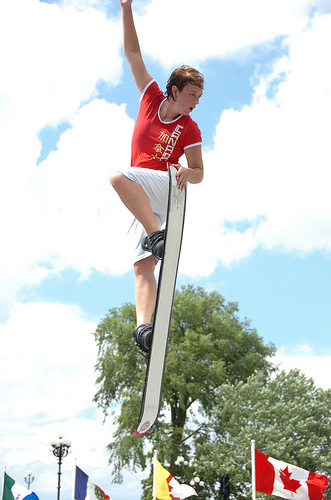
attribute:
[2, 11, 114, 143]
clouds — white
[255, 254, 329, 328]
sky — blue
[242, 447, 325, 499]
canadian flag — red, white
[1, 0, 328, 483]
cloud — large, white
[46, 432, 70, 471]
lights — old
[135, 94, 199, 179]
shirt — red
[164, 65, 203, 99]
hair — short, brown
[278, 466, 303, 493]
maple leaf — red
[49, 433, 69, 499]
street lamp — tall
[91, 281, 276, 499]
tree — large, green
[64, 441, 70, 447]
globe — white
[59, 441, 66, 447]
globe — white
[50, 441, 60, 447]
globe — white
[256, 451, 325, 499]
flag — white, red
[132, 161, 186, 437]
ski — long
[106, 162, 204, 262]
shorts — white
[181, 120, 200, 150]
sleeve — short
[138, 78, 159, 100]
sleeve — short